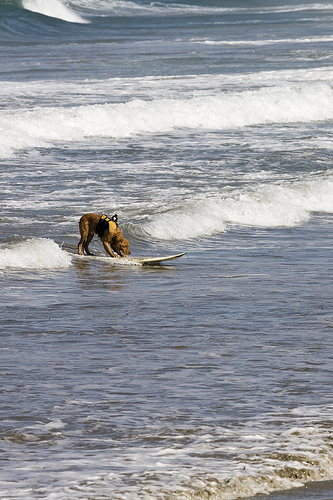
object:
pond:
[0, 1, 332, 499]